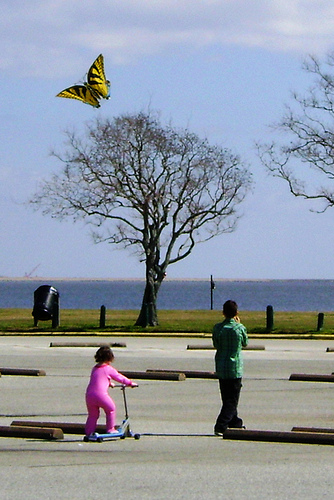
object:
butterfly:
[53, 53, 113, 112]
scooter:
[83, 375, 142, 445]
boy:
[208, 295, 249, 435]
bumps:
[0, 417, 66, 444]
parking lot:
[0, 334, 333, 499]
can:
[30, 284, 60, 330]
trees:
[21, 92, 258, 329]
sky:
[0, 0, 333, 281]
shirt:
[208, 317, 249, 383]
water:
[0, 278, 333, 310]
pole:
[207, 275, 217, 312]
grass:
[1, 308, 333, 334]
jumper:
[82, 362, 131, 434]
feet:
[104, 427, 120, 442]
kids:
[79, 341, 133, 446]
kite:
[53, 48, 113, 112]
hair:
[220, 297, 240, 322]